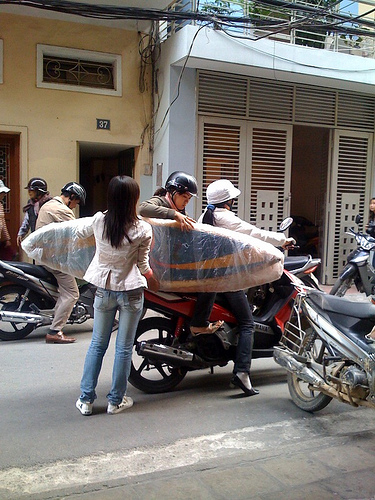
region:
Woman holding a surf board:
[24, 208, 291, 284]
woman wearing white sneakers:
[102, 389, 137, 417]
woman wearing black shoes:
[229, 368, 261, 399]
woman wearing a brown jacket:
[83, 208, 156, 291]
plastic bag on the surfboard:
[22, 220, 280, 293]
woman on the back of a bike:
[159, 165, 230, 333]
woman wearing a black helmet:
[163, 165, 202, 210]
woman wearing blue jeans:
[74, 280, 134, 415]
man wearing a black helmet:
[60, 179, 85, 202]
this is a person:
[74, 179, 150, 414]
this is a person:
[143, 175, 206, 222]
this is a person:
[206, 182, 283, 397]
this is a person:
[40, 181, 85, 339]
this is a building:
[154, 18, 359, 288]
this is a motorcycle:
[275, 278, 372, 391]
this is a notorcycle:
[134, 250, 318, 367]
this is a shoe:
[64, 395, 97, 418]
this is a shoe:
[105, 396, 136, 414]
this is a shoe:
[231, 376, 262, 396]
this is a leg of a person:
[109, 309, 134, 414]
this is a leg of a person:
[76, 308, 107, 414]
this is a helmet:
[165, 169, 204, 191]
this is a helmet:
[61, 180, 93, 202]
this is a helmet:
[29, 177, 49, 196]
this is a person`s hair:
[99, 173, 140, 246]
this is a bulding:
[0, 11, 373, 299]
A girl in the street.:
[73, 174, 161, 415]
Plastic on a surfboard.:
[17, 213, 283, 294]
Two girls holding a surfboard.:
[20, 170, 285, 415]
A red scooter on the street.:
[126, 214, 323, 392]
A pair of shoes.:
[75, 394, 135, 415]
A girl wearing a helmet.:
[137, 170, 225, 340]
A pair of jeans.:
[79, 285, 144, 405]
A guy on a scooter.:
[0, 182, 121, 344]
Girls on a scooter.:
[127, 170, 324, 396]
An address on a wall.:
[95, 116, 110, 130]